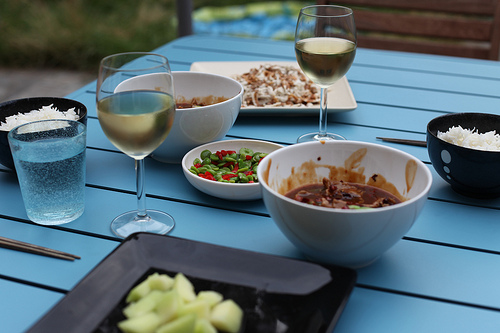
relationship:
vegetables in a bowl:
[192, 148, 264, 182] [176, 134, 283, 202]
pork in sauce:
[313, 190, 353, 209] [366, 180, 398, 207]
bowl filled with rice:
[425, 110, 499, 202] [435, 125, 499, 150]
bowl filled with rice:
[425, 110, 499, 202] [1, 102, 78, 129]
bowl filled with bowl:
[425, 110, 499, 202] [0, 95, 87, 173]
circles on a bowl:
[439, 146, 454, 184] [422, 106, 499, 196]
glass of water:
[6, 118, 86, 228] [24, 138, 79, 210]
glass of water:
[6, 118, 86, 228] [10, 150, 86, 220]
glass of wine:
[92, 50, 175, 235] [95, 90, 172, 160]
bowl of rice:
[0, 95, 91, 181] [2, 99, 82, 130]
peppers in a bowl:
[185, 142, 267, 184] [176, 134, 283, 202]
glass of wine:
[289, 3, 363, 145] [293, 36, 356, 87]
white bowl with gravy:
[280, 114, 412, 270] [284, 173, 404, 211]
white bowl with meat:
[280, 114, 412, 270] [291, 174, 399, 213]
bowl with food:
[180, 136, 282, 202] [119, 267, 241, 332]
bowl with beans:
[112, 69, 247, 158] [172, 100, 213, 107]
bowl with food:
[112, 69, 247, 164] [173, 94, 230, 111]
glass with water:
[6, 118, 86, 228] [12, 137, 85, 226]